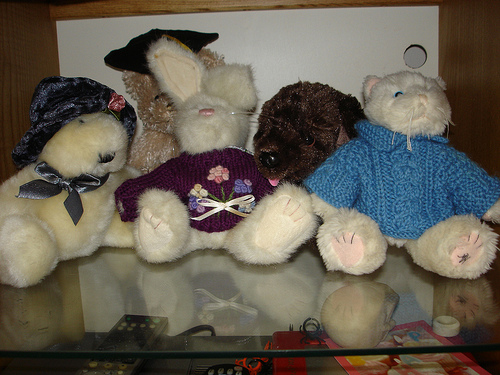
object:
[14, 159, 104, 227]
bow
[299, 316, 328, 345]
spider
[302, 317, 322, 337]
ring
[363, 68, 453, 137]
face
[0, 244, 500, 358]
shelf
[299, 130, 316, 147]
brown eye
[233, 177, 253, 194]
flower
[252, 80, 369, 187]
dog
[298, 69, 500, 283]
animal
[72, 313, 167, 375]
remote control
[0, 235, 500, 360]
glass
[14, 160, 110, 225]
tie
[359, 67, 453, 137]
head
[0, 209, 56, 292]
leg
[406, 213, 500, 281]
leg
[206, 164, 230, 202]
design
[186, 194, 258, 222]
bow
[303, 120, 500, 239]
sweater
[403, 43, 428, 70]
hole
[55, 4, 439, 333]
board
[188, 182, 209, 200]
flower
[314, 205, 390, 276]
foot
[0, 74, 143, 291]
cat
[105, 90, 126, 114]
rose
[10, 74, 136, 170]
hat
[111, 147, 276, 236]
shirt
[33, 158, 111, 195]
neck